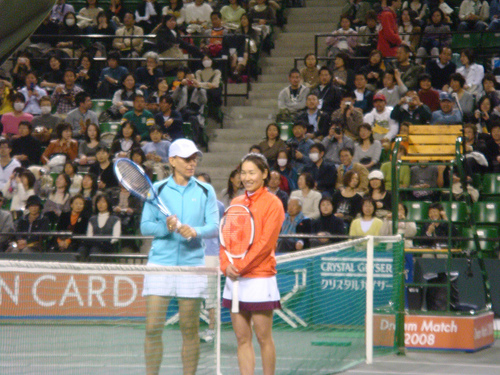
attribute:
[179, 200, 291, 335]
tennis racket — purple, white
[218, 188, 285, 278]
orange jacket — thin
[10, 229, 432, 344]
advertisements — orange, blue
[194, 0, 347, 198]
steps — concrete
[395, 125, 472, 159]
umpire seat — empty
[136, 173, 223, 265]
jacket — blue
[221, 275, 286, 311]
skirt — white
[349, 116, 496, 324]
chair — yellow, green, high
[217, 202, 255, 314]
racquet — red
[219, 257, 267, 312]
skirt — white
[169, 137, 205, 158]
hat — white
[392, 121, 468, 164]
chair — green, tan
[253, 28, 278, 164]
stairs — gray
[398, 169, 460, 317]
ladder — green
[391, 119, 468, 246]
seat — wooden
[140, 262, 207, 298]
shorts — white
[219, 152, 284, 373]
player — female, asian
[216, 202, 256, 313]
racket — upright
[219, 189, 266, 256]
sweater — orange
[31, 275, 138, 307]
card — written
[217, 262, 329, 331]
skirt — white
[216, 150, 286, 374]
woman — wearing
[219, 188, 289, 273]
top — orange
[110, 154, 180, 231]
tennis racket — blue, white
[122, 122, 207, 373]
tennis player — female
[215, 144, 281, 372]
tennis player — female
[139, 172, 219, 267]
jacket — blue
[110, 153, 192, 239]
racket — blue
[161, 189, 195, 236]
top — light blue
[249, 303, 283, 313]
trim — purple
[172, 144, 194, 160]
cap — white